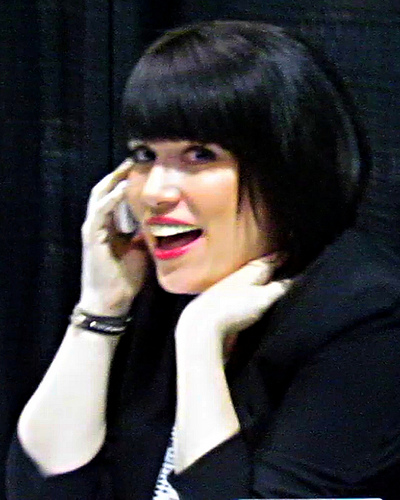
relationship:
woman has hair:
[5, 20, 398, 498] [119, 16, 375, 288]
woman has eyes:
[5, 20, 398, 498] [127, 140, 225, 172]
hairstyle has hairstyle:
[109, 14, 380, 294] [116, 18, 375, 283]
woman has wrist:
[5, 20, 398, 498] [58, 282, 132, 352]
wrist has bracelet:
[58, 282, 132, 352] [68, 303, 137, 337]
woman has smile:
[5, 20, 398, 498] [145, 215, 205, 259]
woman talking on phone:
[5, 20, 398, 498] [111, 198, 138, 235]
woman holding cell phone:
[5, 20, 398, 498] [112, 198, 141, 234]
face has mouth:
[125, 139, 237, 294] [145, 215, 204, 260]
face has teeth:
[125, 139, 237, 294] [149, 221, 196, 239]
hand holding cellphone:
[70, 153, 155, 310] [112, 196, 141, 235]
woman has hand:
[5, 20, 398, 498] [175, 253, 292, 339]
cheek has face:
[121, 168, 171, 214] [119, 40, 319, 286]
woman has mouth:
[5, 20, 398, 498] [117, 207, 219, 277]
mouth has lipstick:
[117, 207, 219, 277] [129, 206, 186, 234]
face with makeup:
[125, 139, 237, 294] [111, 194, 295, 302]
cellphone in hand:
[110, 198, 138, 235] [70, 152, 152, 332]